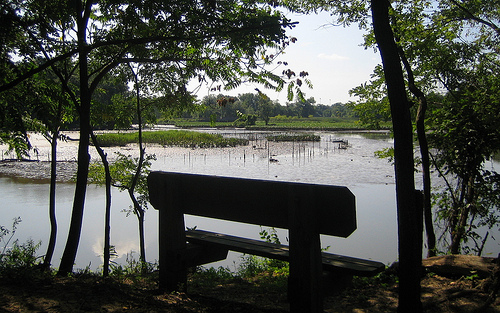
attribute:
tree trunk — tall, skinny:
[361, 7, 448, 297]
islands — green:
[92, 122, 346, 152]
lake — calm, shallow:
[2, 104, 499, 292]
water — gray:
[3, 127, 498, 272]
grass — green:
[162, 110, 452, 131]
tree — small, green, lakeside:
[350, 1, 498, 252]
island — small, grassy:
[94, 128, 253, 151]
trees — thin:
[1, 0, 296, 282]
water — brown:
[22, 140, 399, 253]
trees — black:
[374, 9, 442, 305]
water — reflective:
[270, 139, 400, 187]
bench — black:
[143, 173, 385, 294]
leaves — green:
[397, 9, 448, 69]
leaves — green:
[430, 30, 491, 135]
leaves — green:
[438, 67, 479, 153]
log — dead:
[328, 134, 353, 146]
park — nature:
[35, 13, 405, 290]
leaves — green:
[433, 114, 480, 180]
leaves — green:
[452, 114, 486, 143]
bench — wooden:
[147, 171, 386, 311]